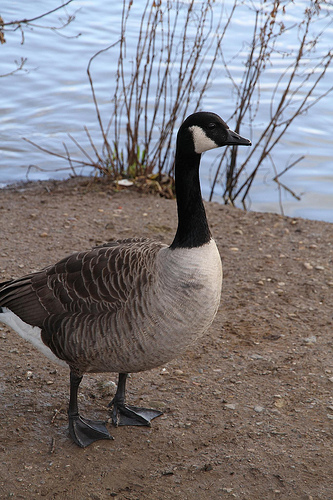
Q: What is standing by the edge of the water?
A: A bird.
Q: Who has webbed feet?
A: The bird.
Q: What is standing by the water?
A: A goose.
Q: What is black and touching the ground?
A: The bird's feet.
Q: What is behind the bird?
A: A body of water.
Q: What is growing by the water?
A: Plants.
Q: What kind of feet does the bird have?
A: Webbed.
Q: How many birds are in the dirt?
A: One.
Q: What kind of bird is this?
A: A goose.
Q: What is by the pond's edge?
A: A goose.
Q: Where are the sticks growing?
A: By the pond.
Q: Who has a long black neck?
A: A goose.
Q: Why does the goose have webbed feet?
A: To swim.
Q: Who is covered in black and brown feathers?
A: The goose.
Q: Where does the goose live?
A: By the water.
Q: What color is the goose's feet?
A: Black.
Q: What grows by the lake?
A: Plants.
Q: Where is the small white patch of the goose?
A: On its neck.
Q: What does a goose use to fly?
A: Its wings.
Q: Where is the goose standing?
A: The riverbank.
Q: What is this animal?
A: A goose.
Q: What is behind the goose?
A: Water.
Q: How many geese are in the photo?
A: One.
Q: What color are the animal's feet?
A: Black.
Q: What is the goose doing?
A: Standing.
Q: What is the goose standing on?
A: Dirt.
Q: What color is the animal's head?
A: Black and whtie.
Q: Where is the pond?
A: Behind the goose.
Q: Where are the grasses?
A: Behind the goose.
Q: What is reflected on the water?
A: Light.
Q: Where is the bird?
A: On land.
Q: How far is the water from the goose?
A: Four feet.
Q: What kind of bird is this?
A: A goose.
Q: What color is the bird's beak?
A: Black.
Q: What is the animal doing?
A: Standing.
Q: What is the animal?
A: A goose.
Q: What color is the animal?
A: Brown and black.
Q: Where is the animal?
A: Near the water.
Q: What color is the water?
A: Blue.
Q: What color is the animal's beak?
A: Black.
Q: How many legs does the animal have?
A: Two.